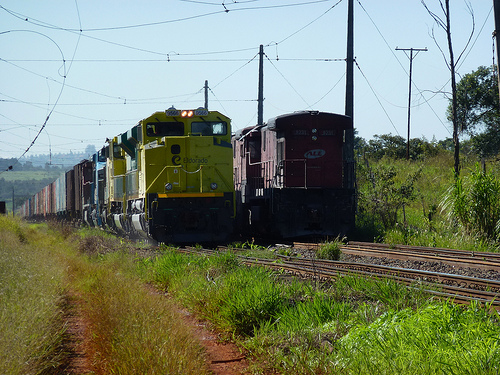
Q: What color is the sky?
A: Blue.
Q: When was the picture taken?
A: Daytime.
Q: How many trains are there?
A: Two.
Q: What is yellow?
A: Train on left.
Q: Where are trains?
A: On train tracks.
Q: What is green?
A: Grass.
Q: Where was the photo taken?
A: Railways.